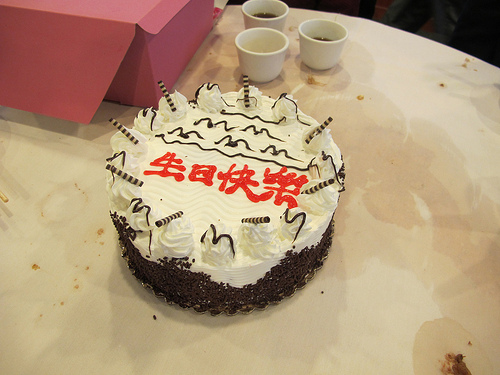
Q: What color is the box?
A: Red.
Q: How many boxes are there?
A: One.